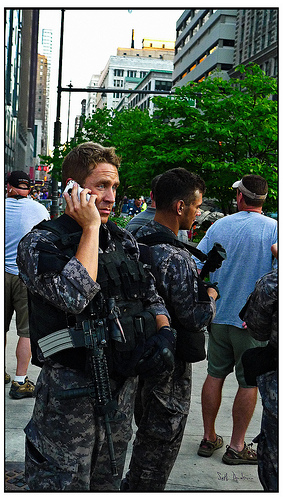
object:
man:
[15, 140, 160, 493]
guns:
[189, 238, 231, 301]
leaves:
[70, 66, 274, 201]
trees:
[56, 83, 272, 221]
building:
[122, 75, 171, 131]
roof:
[123, 69, 171, 79]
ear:
[62, 175, 71, 184]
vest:
[19, 216, 157, 378]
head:
[232, 171, 270, 213]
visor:
[231, 178, 268, 199]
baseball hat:
[5, 168, 30, 193]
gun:
[34, 286, 128, 476]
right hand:
[62, 180, 103, 226]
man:
[188, 169, 279, 465]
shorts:
[4, 269, 34, 339]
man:
[3, 169, 54, 400]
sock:
[12, 373, 30, 383]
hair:
[60, 139, 121, 182]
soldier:
[121, 166, 217, 491]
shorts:
[206, 319, 268, 387]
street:
[6, 307, 267, 490]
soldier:
[235, 241, 279, 491]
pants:
[22, 351, 140, 489]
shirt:
[187, 209, 276, 327]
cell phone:
[59, 178, 95, 209]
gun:
[129, 311, 155, 372]